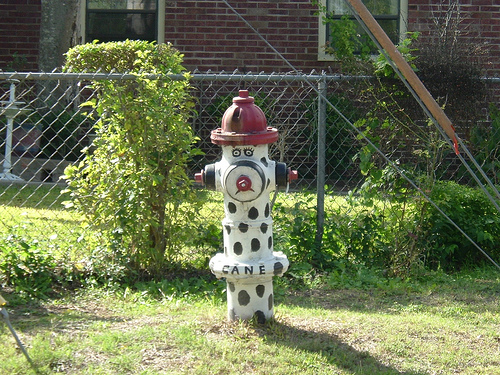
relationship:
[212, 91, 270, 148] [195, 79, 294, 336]
top of hydrant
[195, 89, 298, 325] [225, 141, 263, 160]
fire hydrant has eyes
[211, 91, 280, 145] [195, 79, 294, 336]
top of hydrant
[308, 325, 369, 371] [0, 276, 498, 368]
shadow on ground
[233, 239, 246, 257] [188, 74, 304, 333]
dalmation on firehydrant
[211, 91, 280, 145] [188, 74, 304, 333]
top of firehydrant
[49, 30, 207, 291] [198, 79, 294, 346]
bush behind fire hydrant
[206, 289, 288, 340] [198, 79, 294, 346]
base of fire hydrant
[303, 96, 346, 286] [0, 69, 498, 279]
pole of fence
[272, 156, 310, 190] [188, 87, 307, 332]
nozzle of fire hydrant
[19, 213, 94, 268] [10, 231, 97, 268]
light reflecting on leaves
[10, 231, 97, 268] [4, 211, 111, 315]
leaves on bushes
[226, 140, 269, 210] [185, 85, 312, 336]
face on hydrant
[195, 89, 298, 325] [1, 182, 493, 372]
fire hydrant on grass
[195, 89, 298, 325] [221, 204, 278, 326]
fire hydrant with spots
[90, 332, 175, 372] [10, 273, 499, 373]
clumps of grass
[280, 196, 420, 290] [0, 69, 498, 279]
plants growing on fence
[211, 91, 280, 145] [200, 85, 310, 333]
top of hydrant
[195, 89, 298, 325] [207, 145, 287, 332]
fire hydrant painted like a dalmation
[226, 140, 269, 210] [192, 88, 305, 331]
face on hydrant